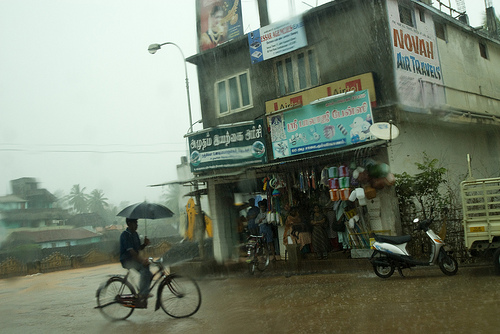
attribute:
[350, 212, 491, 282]
scooter — silver, parked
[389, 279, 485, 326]
droplets —  Small,  water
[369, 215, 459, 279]
motorbike — white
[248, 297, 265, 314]
droplets — small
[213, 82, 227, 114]
window — white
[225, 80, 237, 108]
window — white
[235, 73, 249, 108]
window — white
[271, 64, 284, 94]
window — white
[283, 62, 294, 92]
window — white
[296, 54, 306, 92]
window — white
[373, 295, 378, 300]
droplet — small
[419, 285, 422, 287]
droplet — small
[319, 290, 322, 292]
droplet — small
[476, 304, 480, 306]
droplet — small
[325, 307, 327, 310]
droplet — small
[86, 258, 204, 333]
bicycle — man's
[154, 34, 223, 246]
lamp post —  tall,  lamp's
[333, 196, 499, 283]
scooter —  parked 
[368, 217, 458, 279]
scooter —  parked ,  outside,   in the rain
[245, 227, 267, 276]
bike — red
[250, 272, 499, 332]
water droplets — small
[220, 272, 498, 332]
water droplets — small